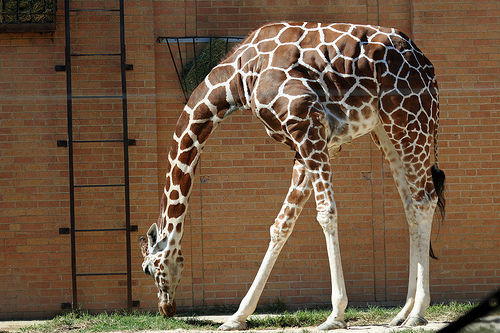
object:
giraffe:
[138, 15, 448, 331]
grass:
[19, 311, 219, 330]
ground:
[1, 310, 498, 332]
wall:
[1, 0, 499, 317]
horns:
[138, 235, 149, 258]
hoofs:
[403, 316, 429, 326]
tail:
[430, 107, 448, 243]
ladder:
[52, 0, 143, 316]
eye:
[144, 264, 151, 277]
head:
[135, 224, 188, 319]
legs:
[285, 115, 354, 333]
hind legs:
[378, 128, 435, 330]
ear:
[144, 222, 160, 247]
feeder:
[156, 34, 244, 101]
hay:
[178, 38, 232, 99]